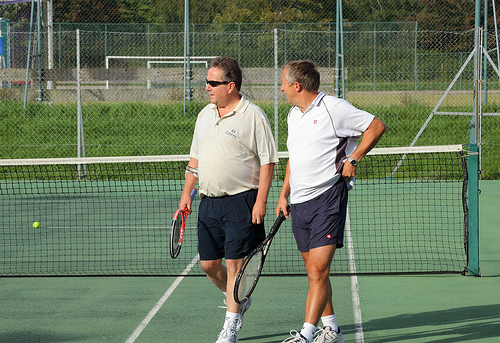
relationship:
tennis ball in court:
[33, 221, 40, 228] [2, 1, 500, 343]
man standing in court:
[179, 58, 281, 342] [2, 1, 500, 343]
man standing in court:
[276, 60, 387, 342] [2, 1, 500, 343]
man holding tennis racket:
[179, 58, 281, 342] [170, 187, 198, 259]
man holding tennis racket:
[276, 60, 387, 342] [233, 204, 291, 304]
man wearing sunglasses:
[179, 58, 281, 342] [206, 79, 229, 87]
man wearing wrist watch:
[276, 60, 387, 342] [347, 156, 359, 167]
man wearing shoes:
[179, 58, 281, 342] [214, 294, 251, 343]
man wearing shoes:
[276, 60, 387, 342] [281, 325, 347, 342]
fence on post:
[1, 28, 500, 181] [273, 28, 279, 180]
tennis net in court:
[1, 144, 470, 278] [2, 1, 500, 343]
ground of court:
[0, 179, 499, 343] [2, 1, 500, 343]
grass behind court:
[0, 81, 499, 182] [2, 1, 500, 343]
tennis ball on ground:
[33, 221, 40, 228] [0, 179, 499, 343]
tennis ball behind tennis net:
[33, 221, 40, 228] [1, 144, 470, 278]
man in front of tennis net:
[179, 58, 281, 342] [1, 144, 470, 278]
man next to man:
[179, 58, 281, 342] [276, 60, 387, 342]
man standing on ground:
[179, 58, 281, 342] [0, 179, 499, 343]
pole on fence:
[75, 29, 83, 180] [1, 28, 500, 181]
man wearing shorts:
[179, 58, 281, 342] [198, 189, 266, 261]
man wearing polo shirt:
[179, 58, 281, 342] [188, 91, 280, 200]